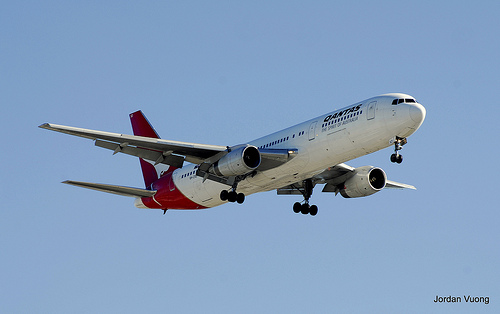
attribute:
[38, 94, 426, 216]
airplane — mid-flight, red grey, white, flying through air, reflecting sun, red on black, flying, red, painted red, whit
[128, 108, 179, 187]
tail — back of airplane, red, white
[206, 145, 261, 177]
engine — turbine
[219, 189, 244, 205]
wheels — down, extended, landing gear, black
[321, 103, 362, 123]
logo — qantas, painted on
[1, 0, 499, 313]
sky — cloud free, clear, blue, here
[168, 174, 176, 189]
door — emergency door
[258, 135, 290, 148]
passenger windows — on side of airplane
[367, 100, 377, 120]
door — closed, front door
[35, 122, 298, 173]
left wing — silver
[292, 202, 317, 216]
wheels — extended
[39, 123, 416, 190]
wings — large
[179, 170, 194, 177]
windows — on side of airplane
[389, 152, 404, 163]
wheels — extended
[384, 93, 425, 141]
nose — white, tip of airplane, front of airplane